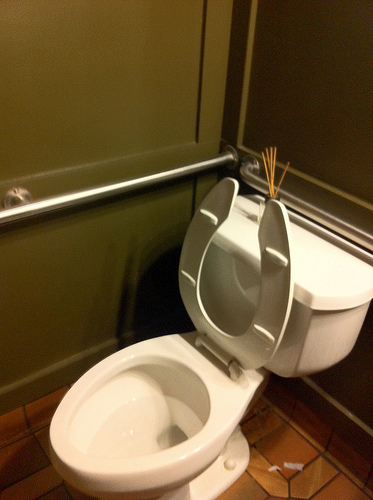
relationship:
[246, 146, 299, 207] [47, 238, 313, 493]
wooden sticks on toilet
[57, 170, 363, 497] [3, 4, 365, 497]
toilet in bathroom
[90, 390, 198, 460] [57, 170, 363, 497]
water in toilet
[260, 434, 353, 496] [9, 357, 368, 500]
tile on floor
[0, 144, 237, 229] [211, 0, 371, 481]
railing on wall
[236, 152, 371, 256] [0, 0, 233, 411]
railing on wall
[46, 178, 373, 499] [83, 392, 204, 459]
toilet containing water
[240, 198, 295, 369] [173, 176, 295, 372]
edge bordering lid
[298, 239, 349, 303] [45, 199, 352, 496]
tank mounted on toilet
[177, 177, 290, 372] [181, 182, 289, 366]
underside belonging to seat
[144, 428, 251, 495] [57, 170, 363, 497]
bottom holding up toilet